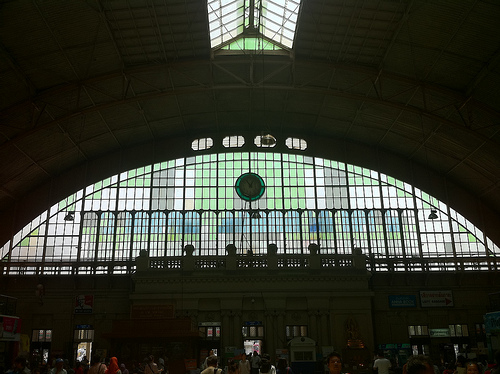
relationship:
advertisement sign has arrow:
[414, 284, 456, 312] [441, 294, 455, 309]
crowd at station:
[5, 334, 498, 371] [6, 4, 498, 372]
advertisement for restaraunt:
[72, 288, 89, 314] [121, 248, 386, 371]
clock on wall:
[231, 167, 270, 201] [20, 132, 488, 266]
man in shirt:
[370, 344, 395, 372] [373, 351, 393, 366]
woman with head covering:
[102, 354, 124, 372] [108, 355, 118, 367]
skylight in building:
[198, 1, 311, 58] [8, 3, 494, 368]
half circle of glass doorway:
[0, 153, 497, 269] [0, 151, 500, 271]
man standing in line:
[370, 351, 396, 373] [12, 360, 489, 372]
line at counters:
[12, 360, 489, 372] [17, 310, 488, 355]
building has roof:
[50, 34, 498, 334] [7, 4, 494, 93]